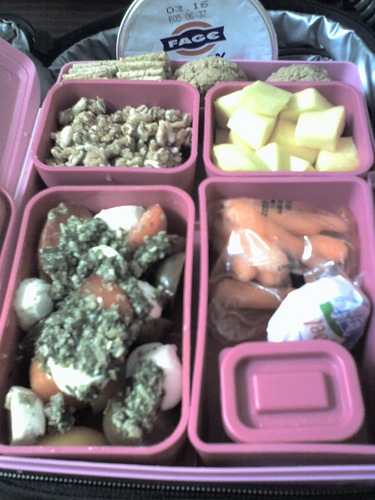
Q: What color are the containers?
A: Pink.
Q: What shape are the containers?
A: Rectangular.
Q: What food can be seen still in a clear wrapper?
A: Baby carrots.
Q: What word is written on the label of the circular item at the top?
A: FAGE.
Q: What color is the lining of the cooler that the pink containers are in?
A: Silver.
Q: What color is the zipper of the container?
A: Black.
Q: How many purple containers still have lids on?
A: One.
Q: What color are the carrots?
A: Orange.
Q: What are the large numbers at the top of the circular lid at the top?
A: 03 16.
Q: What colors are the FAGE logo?
A: Red white and blue.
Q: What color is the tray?
A: Pink.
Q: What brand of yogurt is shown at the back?
A: Fage.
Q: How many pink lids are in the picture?
A: 1.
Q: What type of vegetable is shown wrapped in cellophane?
A: Carrots.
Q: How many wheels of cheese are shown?
A: 1.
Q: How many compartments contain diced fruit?
A: 1.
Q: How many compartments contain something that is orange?
A: 2.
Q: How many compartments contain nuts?
A: 1.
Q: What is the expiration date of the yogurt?
A: 03.16.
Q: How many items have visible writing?
A: 3.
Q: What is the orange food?
A: Carrots.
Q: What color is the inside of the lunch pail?
A: Silver.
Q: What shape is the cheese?
A: Circle.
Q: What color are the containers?
A: Purple.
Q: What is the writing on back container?
A: Fage.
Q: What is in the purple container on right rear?
A: Apple pieces.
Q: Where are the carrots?
A: In front right container.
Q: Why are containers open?
A: To eat.